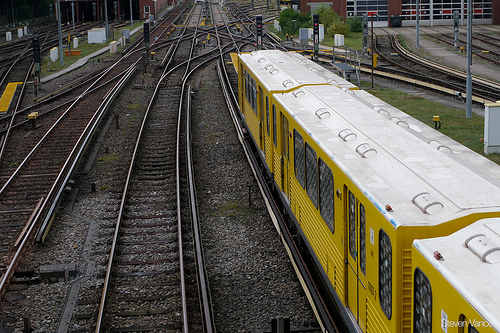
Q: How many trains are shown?
A: One.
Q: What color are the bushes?
A: Green.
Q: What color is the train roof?
A: Silver.